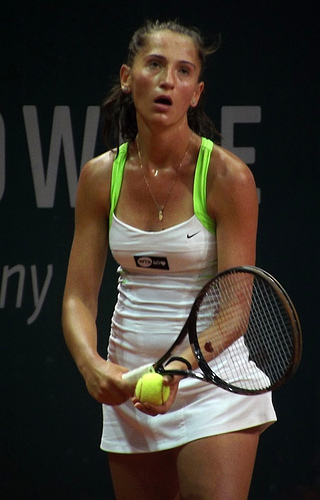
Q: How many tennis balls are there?
A: One.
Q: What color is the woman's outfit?
A: White and green.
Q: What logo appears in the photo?
A: Nike.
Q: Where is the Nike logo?
A: On the top part of the woman's dress.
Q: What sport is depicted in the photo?
A: Tennis.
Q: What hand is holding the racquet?
A: Right.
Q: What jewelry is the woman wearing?
A: A necklace.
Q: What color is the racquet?
A: Black with a white handle.